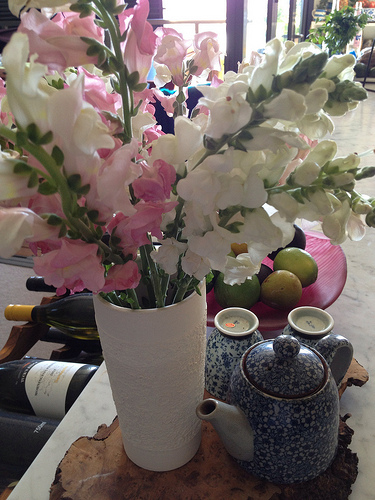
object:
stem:
[104, 5, 170, 306]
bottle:
[1, 291, 105, 349]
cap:
[1, 300, 35, 323]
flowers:
[257, 81, 308, 130]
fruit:
[271, 245, 319, 286]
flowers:
[108, 197, 164, 260]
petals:
[149, 185, 151, 189]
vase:
[90, 260, 209, 476]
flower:
[24, 237, 105, 297]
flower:
[175, 151, 220, 221]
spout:
[191, 387, 250, 448]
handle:
[311, 326, 354, 386]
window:
[154, 0, 228, 86]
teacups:
[196, 308, 340, 488]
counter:
[352, 237, 371, 370]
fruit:
[256, 266, 304, 313]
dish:
[205, 227, 348, 331]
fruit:
[211, 265, 261, 310]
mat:
[80, 473, 257, 491]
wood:
[60, 388, 340, 492]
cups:
[207, 296, 267, 396]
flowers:
[100, 258, 146, 296]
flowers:
[183, 26, 222, 81]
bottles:
[0, 347, 103, 416]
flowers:
[126, 145, 180, 209]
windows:
[242, 0, 269, 63]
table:
[19, 358, 97, 500]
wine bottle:
[0, 405, 57, 491]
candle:
[282, 294, 339, 346]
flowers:
[315, 187, 352, 253]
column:
[213, 4, 248, 69]